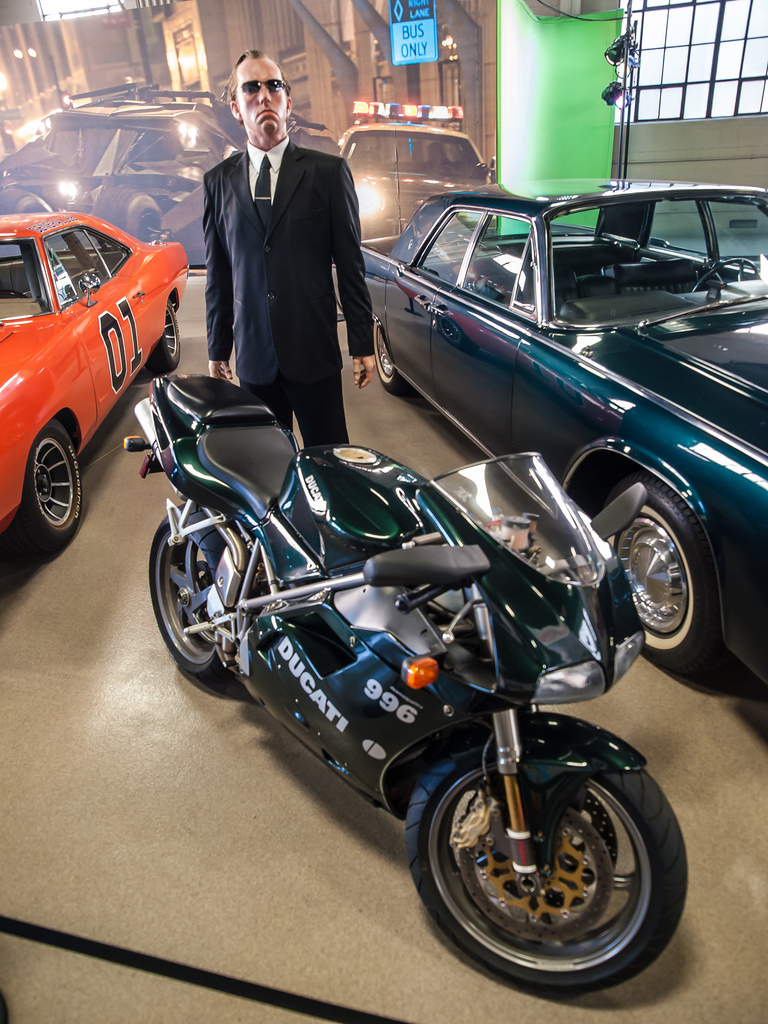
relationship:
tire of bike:
[415, 716, 697, 1002] [122, 378, 689, 996]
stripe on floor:
[2, 913, 398, 1020] [2, 275, 765, 1020]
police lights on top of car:
[347, 98, 464, 123] [335, 118, 498, 243]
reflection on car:
[385, 275, 520, 372] [354, 181, 765, 685]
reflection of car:
[385, 275, 520, 372] [0, 206, 194, 541]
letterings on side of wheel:
[64, 444, 83, 520] [18, 424, 83, 549]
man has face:
[199, 49, 376, 448] [231, 51, 291, 145]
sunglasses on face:
[233, 79, 287, 94] [231, 51, 291, 145]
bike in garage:
[122, 378, 689, 996] [0, 0, 763, 1019]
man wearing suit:
[199, 49, 376, 448] [200, 144, 371, 447]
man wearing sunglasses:
[199, 49, 376, 448] [242, 79, 286, 92]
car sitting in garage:
[354, 181, 765, 685] [0, 0, 763, 1019]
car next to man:
[354, 181, 765, 685] [199, 49, 376, 448]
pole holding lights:
[619, 7, 632, 178] [600, 29, 641, 108]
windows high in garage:
[617, 0, 766, 125] [0, 0, 763, 1019]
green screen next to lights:
[501, 1, 612, 230] [600, 1, 637, 182]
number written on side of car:
[97, 300, 144, 390] [0, 206, 194, 541]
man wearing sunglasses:
[199, 49, 376, 448] [237, 79, 284, 94]